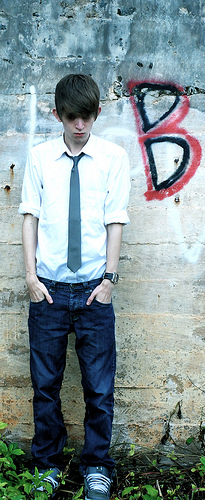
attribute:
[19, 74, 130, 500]
young man — looking down, standing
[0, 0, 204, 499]
wall — stone, grey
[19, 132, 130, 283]
shirt — white, for dress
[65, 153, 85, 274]
tie — grey, thin, gray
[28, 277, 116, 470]
jeans — denim, dark blue, blue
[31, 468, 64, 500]
skater shoe — white laced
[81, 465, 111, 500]
skater shoe — white laced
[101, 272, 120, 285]
watch — large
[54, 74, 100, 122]
hair — short, brown, covering eyes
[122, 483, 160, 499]
plants — small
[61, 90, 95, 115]
bangs — long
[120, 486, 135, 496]
leaf — green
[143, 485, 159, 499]
leaf — green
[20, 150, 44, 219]
sleeve — rolled up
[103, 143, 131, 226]
sleeve — rolled up